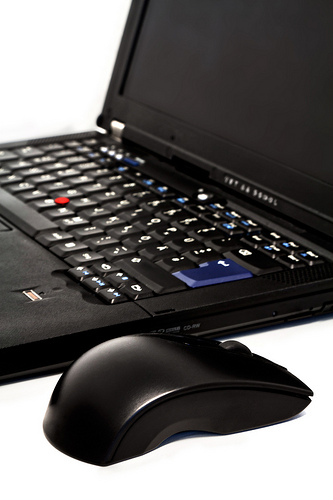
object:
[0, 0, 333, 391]
computer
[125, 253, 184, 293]
shift key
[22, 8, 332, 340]
thinkpad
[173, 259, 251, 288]
button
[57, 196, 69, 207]
cursor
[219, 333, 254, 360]
mouse wheel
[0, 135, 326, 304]
key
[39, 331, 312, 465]
black mouse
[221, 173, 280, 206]
company name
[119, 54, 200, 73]
wall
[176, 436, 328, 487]
table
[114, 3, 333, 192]
monitor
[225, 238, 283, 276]
backspace key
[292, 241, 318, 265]
button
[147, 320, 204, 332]
writing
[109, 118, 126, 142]
hinges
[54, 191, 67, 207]
pointing stick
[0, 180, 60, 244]
spacebar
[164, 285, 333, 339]
drive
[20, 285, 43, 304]
print scanner